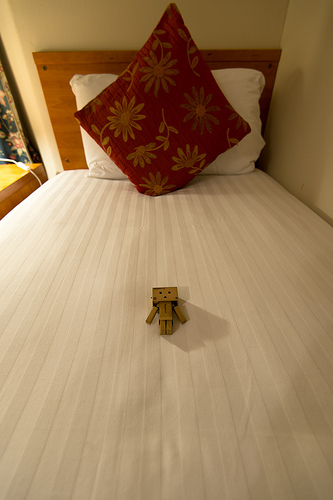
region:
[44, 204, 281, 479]
this is a bed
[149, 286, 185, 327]
this is a doll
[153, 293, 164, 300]
the doll is brown in color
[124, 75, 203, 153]
this is a pillow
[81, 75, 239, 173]
the pillows are two in number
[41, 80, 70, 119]
the bed is wooden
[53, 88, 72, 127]
the wood part is brown in color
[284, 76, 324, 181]
this is a wall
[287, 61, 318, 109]
the wall is cream in color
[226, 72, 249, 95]
the pillow is white in color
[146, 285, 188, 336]
Wooden toy on bed.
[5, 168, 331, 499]
Bed spread has stripes.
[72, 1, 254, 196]
Pillow has flowers.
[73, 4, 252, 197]
Pillow is mainly red.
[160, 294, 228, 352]
Shadow of toy on bed spread.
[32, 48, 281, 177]
Wooden headboard at top of bed.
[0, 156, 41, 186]
Cord hanging down from table.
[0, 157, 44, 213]
Bedside table next to bed.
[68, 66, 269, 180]
White pillow on bed.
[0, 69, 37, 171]
Floral print on bedside table.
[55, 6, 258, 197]
pillow is burgundy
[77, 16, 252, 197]
pillow has a floral pattern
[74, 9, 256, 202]
pillow is diamond shaped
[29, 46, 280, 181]
headboard is wooden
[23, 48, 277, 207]
headboard is brown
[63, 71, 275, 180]
pillow is white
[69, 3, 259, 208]
pillow is standing up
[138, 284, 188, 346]
wooden figurine on bed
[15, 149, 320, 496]
bed has a white sheet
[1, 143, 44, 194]
white cord next to the bed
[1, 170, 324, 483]
a narrow little bed in the room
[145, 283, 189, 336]
a cute but tiny robot laying on the bed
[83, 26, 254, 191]
a red pillow with gold flowers on it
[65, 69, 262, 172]
a white pillow behind the red one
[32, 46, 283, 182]
the wooden headboard close to the wall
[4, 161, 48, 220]
a desk next to the bed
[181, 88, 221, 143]
a flower on the pillow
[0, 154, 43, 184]
a light switch hanging on the desk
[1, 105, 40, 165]
a curtain hanging on the wall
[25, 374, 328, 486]
a white blanket sitting on the bed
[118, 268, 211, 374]
wooden figure on bed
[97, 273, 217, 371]
wooden figure with black dot eyes on bed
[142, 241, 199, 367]
wooden figure with black dot nose on bed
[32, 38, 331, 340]
bed with brown head board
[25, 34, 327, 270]
bed with two pillows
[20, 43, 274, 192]
red pillow with gold flowers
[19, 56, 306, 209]
white pillow with red pillow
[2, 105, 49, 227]
white wire in photo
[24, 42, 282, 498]
bed with white comforter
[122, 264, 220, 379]
wooden figure in center of bed